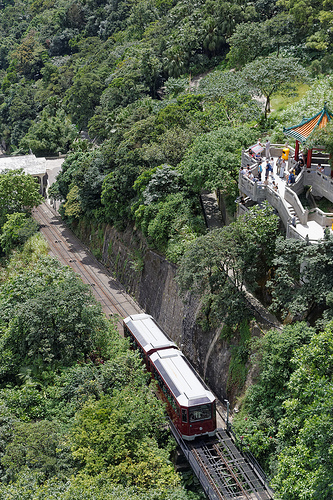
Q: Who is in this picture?
A: Multiple people.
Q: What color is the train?
A: Red and white.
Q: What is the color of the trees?
A: Multiple colors of green.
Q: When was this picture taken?
A: In the daytime.